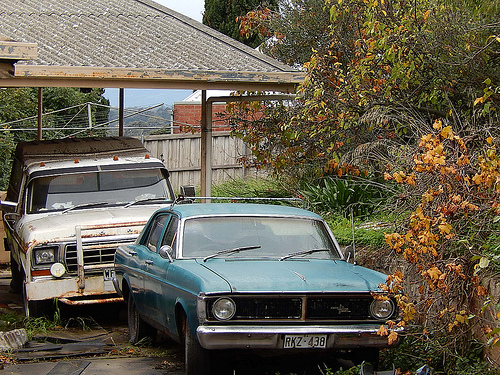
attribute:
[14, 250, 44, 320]
tires — flat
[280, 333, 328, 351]
license plate — white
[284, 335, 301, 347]
lettering — black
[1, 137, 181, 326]
vehicle — one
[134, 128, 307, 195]
fence — wooden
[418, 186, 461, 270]
leaves — dying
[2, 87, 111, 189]
tree — green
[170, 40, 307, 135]
house — red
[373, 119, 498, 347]
leaves — yellow, orange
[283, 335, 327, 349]
license plate — old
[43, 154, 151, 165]
orange lights — four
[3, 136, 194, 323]
truck — white, rusty, old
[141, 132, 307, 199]
fence — wooden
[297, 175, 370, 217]
plant — pointy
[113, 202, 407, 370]
car — blue, pale blue, old, sedan style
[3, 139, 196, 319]
vehicle — one, white